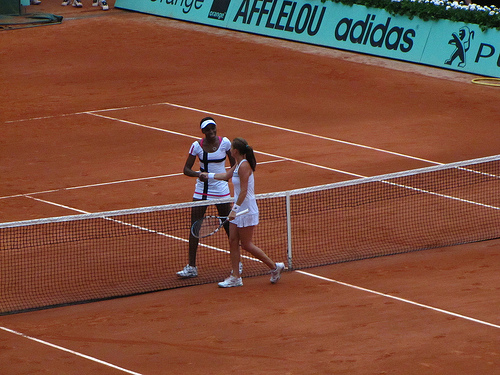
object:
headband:
[199, 117, 221, 141]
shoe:
[219, 272, 250, 289]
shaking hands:
[187, 164, 210, 183]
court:
[0, 0, 499, 375]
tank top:
[230, 155, 261, 227]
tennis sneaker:
[174, 264, 200, 280]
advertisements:
[115, 0, 499, 88]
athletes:
[176, 114, 288, 283]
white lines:
[289, 160, 478, 196]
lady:
[176, 113, 239, 278]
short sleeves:
[187, 138, 235, 205]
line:
[19, 193, 499, 329]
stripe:
[188, 144, 194, 156]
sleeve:
[186, 140, 200, 155]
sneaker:
[264, 258, 286, 285]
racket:
[188, 207, 251, 241]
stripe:
[196, 146, 213, 205]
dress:
[187, 135, 240, 201]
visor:
[198, 116, 221, 138]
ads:
[330, 11, 498, 78]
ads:
[142, 0, 327, 38]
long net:
[0, 154, 499, 317]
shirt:
[224, 160, 264, 229]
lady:
[217, 138, 286, 291]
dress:
[226, 158, 263, 228]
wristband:
[199, 170, 221, 181]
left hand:
[224, 207, 241, 223]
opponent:
[211, 137, 287, 290]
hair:
[228, 138, 262, 174]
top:
[0, 153, 500, 229]